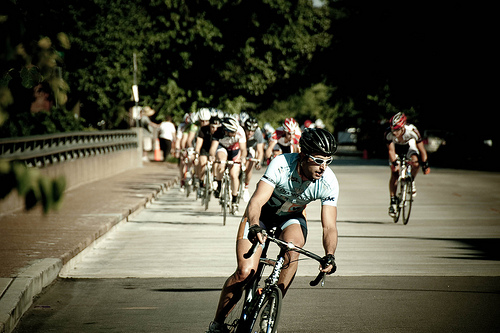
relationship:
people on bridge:
[386, 110, 431, 197] [2, 121, 494, 331]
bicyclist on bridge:
[216, 130, 333, 315] [2, 121, 494, 331]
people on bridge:
[215, 115, 246, 205] [2, 121, 494, 331]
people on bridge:
[271, 117, 299, 160] [2, 121, 494, 331]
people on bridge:
[194, 117, 225, 197] [2, 121, 494, 331]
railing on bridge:
[2, 128, 140, 215] [143, 121, 498, 325]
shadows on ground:
[118, 171, 203, 216] [23, 150, 496, 329]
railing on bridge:
[2, 128, 140, 215] [2, 129, 498, 279]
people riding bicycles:
[158, 99, 428, 329] [163, 153, 414, 323]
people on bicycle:
[177, 104, 313, 196] [165, 152, 257, 219]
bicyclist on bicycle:
[205, 127, 340, 333] [222, 227, 335, 332]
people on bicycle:
[386, 110, 431, 197] [387, 158, 427, 221]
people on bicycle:
[215, 115, 246, 205] [216, 159, 238, 219]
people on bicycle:
[386, 110, 429, 210] [389, 157, 419, 223]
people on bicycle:
[215, 115, 246, 205] [211, 160, 239, 225]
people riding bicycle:
[158, 99, 428, 333] [209, 223, 335, 333]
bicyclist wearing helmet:
[205, 127, 340, 333] [299, 124, 341, 159]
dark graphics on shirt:
[241, 169, 326, 223] [259, 158, 343, 218]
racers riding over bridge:
[129, 101, 436, 332] [9, 131, 494, 322]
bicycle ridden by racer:
[209, 223, 336, 331] [206, 125, 339, 330]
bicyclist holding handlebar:
[205, 127, 340, 333] [236, 226, 329, 287]